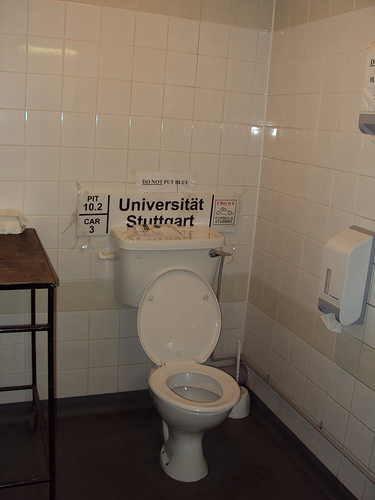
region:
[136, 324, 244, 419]
this is a toilet sink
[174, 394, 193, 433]
the sink is white in color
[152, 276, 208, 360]
this is a the lid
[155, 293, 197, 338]
the lid is white in color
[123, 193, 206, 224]
this is a writing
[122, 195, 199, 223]
the writing is in black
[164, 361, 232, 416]
the sink is opened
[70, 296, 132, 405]
this is the wall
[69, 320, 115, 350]
the wall is made with ties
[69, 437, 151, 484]
this is the floor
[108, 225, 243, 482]
A white toilet in a bathroom.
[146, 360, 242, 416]
A white toilet seat.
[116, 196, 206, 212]
The word Universitat.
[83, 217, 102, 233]
The word CAR 3 on the left side of a sign.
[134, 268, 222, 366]
The back of a white toilet seat.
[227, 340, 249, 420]
A white toilet brush in a holder.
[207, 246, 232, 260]
Silver handle on a white toilet.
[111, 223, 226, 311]
The back white part of a toilet tank.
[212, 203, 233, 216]
A little figure of a car on the left of a sign.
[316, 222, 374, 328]
A gray and white tissue dispensor on the wall.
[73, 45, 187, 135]
the tiles is white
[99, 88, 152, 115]
the tiles is white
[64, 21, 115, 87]
the tiles is white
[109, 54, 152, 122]
the tiles is white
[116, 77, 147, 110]
the tiles is white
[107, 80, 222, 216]
the tiles is white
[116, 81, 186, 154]
the tiles is white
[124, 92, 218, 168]
the tiles is white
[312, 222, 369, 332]
The tissue dispenser mounted on the wall.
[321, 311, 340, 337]
The white tissue coming out of the dispenser on the wall.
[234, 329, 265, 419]
The toilet brush on the right of the toilet.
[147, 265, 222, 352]
The toilet seat lid.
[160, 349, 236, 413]
The toilet seat of the toilet.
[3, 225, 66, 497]
The table to the left of the toilet.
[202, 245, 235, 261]
The toilet handle to flush the toilet.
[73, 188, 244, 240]
The long paper taped to the wall.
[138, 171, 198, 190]
The small white paper above the larger sign taped to the wall.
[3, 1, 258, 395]
The white tiled wall behind the toilet.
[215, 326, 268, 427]
the bowl cleaner is white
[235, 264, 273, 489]
the bowl cleaner is white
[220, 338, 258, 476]
the bowl cleaner is white